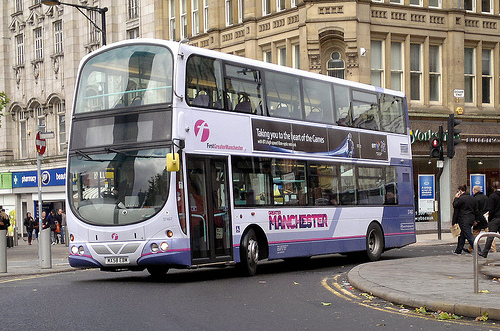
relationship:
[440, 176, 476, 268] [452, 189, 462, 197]
woman on cellphone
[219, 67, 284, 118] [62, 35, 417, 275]
glass window on bus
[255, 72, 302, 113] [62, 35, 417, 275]
window on bus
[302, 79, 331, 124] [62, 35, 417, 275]
window on bus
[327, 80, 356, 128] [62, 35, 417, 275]
window on bus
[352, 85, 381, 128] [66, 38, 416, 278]
window on bus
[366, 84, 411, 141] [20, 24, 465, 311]
window on bus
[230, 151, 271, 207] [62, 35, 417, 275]
window on bus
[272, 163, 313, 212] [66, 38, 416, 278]
window on bus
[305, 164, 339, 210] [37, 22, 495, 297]
window on bus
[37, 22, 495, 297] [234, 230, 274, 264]
bus with tire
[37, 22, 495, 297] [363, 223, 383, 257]
bus with tire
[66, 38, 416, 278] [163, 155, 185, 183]
bus with mirror